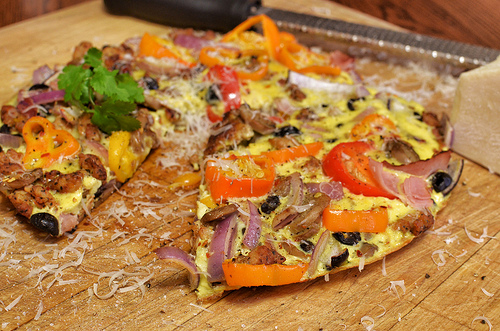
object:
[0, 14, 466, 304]
pizza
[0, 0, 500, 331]
table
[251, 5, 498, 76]
grader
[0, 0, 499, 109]
background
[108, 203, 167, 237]
cheese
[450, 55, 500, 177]
block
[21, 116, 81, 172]
pepper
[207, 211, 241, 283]
onion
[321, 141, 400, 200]
tomato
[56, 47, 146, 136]
parsley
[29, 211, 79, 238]
olives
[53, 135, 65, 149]
slice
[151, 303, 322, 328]
board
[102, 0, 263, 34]
handle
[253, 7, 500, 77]
blade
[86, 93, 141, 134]
lettuce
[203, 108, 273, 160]
chicken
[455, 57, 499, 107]
napkin